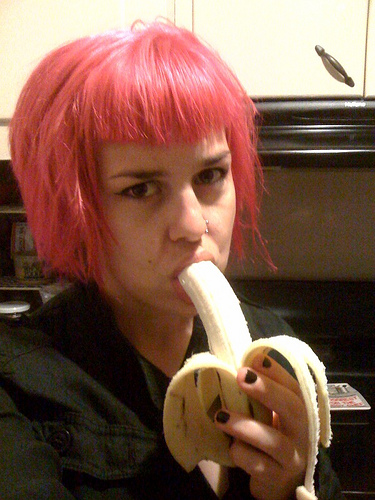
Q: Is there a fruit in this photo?
A: Yes, there is a fruit.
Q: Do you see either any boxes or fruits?
A: Yes, there is a fruit.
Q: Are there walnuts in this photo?
A: No, there are no walnuts.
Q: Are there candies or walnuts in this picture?
A: No, there are no walnuts or candies.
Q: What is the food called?
A: The food is a fruit.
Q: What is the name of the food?
A: The food is a fruit.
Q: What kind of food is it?
A: The food is a fruit.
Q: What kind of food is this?
A: That is a fruit.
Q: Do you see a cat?
A: No, there are no cats.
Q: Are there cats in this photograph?
A: No, there are no cats.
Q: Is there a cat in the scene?
A: No, there are no cats.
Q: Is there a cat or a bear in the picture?
A: No, there are no cats or bears.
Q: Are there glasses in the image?
A: No, there are no glasses.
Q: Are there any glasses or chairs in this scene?
A: No, there are no glasses or chairs.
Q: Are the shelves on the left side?
A: Yes, the shelves are on the left of the image.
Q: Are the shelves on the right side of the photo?
A: No, the shelves are on the left of the image.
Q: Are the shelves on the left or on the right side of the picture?
A: The shelves are on the left of the image.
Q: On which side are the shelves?
A: The shelves are on the left of the image.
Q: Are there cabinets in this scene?
A: Yes, there is a cabinet.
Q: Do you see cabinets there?
A: Yes, there is a cabinet.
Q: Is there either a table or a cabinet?
A: Yes, there is a cabinet.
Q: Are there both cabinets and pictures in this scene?
A: No, there is a cabinet but no pictures.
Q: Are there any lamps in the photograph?
A: No, there are no lamps.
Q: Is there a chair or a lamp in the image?
A: No, there are no lamps or chairs.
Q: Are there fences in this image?
A: No, there are no fences.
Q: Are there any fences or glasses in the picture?
A: No, there are no fences or glasses.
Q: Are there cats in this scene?
A: No, there are no cats.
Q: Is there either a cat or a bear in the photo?
A: No, there are no cats or bears.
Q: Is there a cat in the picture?
A: No, there are no cats.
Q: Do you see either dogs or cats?
A: No, there are no cats or dogs.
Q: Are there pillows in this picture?
A: No, there are no pillows.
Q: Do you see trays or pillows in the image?
A: No, there are no pillows or trays.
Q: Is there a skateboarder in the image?
A: No, there are no skateboarders.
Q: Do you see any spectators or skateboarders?
A: No, there are no skateboarders or spectators.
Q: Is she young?
A: Yes, the girl is young.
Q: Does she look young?
A: Yes, the girl is young.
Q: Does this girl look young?
A: Yes, the girl is young.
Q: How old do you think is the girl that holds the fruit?
A: The girl is young.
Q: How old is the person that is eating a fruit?
A: The girl is young.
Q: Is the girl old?
A: No, the girl is young.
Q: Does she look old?
A: No, the girl is young.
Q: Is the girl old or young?
A: The girl is young.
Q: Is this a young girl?
A: Yes, this is a young girl.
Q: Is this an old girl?
A: No, this is a young girl.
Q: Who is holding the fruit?
A: The girl is holding the fruit.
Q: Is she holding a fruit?
A: Yes, the girl is holding a fruit.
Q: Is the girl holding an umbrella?
A: No, the girl is holding a fruit.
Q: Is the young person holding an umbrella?
A: No, the girl is holding a fruit.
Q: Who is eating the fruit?
A: The girl is eating the fruit.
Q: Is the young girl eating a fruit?
A: Yes, the girl is eating a fruit.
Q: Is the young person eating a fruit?
A: Yes, the girl is eating a fruit.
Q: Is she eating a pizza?
A: No, the girl is eating a fruit.